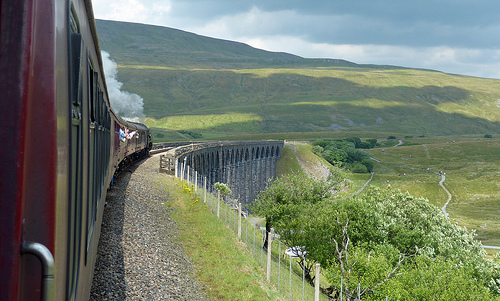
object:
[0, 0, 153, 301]
train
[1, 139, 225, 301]
track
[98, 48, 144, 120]
smoke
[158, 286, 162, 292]
rocks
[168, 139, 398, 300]
fence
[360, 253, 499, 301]
tree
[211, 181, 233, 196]
leaves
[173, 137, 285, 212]
bridge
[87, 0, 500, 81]
sky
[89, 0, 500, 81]
clouds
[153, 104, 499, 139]
shadows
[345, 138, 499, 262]
grass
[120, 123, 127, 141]
person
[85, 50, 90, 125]
window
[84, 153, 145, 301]
shadow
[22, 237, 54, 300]
pole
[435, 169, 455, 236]
water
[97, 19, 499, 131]
hill